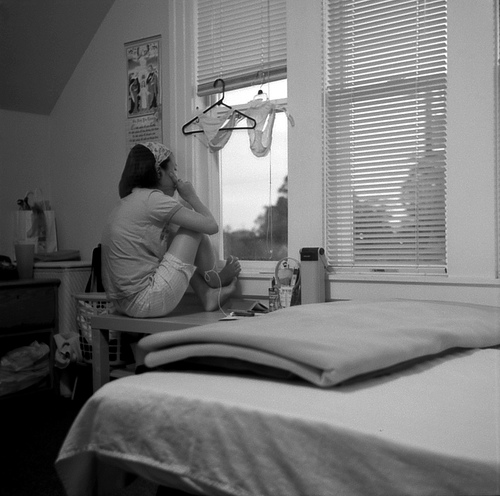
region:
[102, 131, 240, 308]
Listening favorite tunes table.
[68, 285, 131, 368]
Laundry hamper full wash.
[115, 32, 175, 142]
Wall calendar reminds to do.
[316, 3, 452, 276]
Window blinds complete coverage.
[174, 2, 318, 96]
Second window blind half way.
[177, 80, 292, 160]
Two pair panties drying hanger.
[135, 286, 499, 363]
Blanket folded until dark.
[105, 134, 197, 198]
Bandana hold hair back.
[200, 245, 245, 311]
Bare feet against windowsill.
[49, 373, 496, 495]
Bed sheet under blanket.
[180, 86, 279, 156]
laundry hanging to dry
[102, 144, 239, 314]
girl sitting on a table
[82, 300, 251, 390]
table holding up a girl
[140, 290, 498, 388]
a blanket on a bed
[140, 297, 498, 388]
a blanket on the foot of a bed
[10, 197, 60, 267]
a bag in the corner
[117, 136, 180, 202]
girl with a scarf on her head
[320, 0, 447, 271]
a set of thin blinds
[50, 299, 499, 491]
a bed in the room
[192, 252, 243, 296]
a girl with a string around her leg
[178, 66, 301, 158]
Underwear hanging in window to dry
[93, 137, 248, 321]
Girl sitting on desk looking out window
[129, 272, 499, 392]
Blankets folded on a bed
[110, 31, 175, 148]
Poster on the wall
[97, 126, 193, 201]
Bandana in girls hair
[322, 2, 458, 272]
Blinds over a window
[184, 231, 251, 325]
Headphone plugged into mp3 player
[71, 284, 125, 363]
Laundry basket filled with clothes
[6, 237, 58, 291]
cup on a shelf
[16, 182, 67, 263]
Shopping bag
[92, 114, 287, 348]
a girl looks out a window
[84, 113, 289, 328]
a girl sits on a table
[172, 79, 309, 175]
clothing is hung on hangers in front of the window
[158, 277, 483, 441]
blankets are stacked on the bed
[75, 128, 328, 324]
the girl is wearing a bandanna in her hair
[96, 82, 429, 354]
a girl sits on a table looking out a window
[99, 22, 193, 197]
a poster hanging on a wall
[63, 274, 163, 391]
a basket of clothing on the floor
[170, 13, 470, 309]
blinds on windows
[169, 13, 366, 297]
the blinds are partly open on the window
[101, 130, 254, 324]
Girl sitting on table with back to room.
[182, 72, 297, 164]
Washed underwear hanging from hangers on window.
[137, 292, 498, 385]
Blanket folded at foot of bed.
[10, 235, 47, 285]
Plastic cup sitting on dresser.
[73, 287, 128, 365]
Clothes hamper sitting in corner of room.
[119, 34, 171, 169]
Poster mounted on wall near window,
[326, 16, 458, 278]
Mini blinds over window.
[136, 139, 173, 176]
Young girl wearing scarf around head.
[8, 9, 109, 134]
Sloped ceiling of room.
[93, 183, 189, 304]
Young girl dressed in t-shirt.